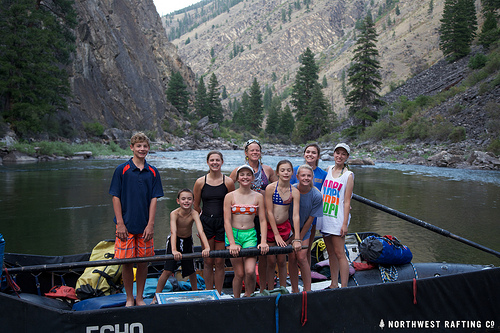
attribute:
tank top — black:
[196, 172, 231, 240]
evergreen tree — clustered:
[166, 67, 189, 110]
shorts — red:
[266, 221, 292, 242]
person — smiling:
[108, 132, 160, 304]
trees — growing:
[1, 0, 498, 140]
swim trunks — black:
[162, 235, 194, 273]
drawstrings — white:
[179, 238, 182, 253]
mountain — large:
[6, 3, 178, 127]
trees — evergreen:
[165, 47, 343, 139]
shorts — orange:
[105, 231, 162, 268]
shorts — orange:
[111, 230, 161, 269]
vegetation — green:
[0, 0, 77, 145]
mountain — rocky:
[1, 0, 221, 153]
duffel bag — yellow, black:
[70, 238, 117, 302]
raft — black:
[1, 245, 499, 331]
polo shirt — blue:
[105, 156, 163, 229]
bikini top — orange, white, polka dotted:
[231, 202, 256, 212]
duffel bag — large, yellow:
[77, 241, 134, 306]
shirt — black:
[199, 173, 230, 230]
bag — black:
[357, 232, 413, 269]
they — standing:
[9, 139, 494, 329]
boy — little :
[161, 185, 212, 282]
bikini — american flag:
[274, 181, 294, 201]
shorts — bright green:
[222, 223, 259, 249]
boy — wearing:
[101, 114, 168, 306]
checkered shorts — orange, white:
[110, 224, 155, 262]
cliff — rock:
[81, 17, 204, 136]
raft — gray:
[51, 255, 230, 313]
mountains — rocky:
[93, 25, 286, 102]